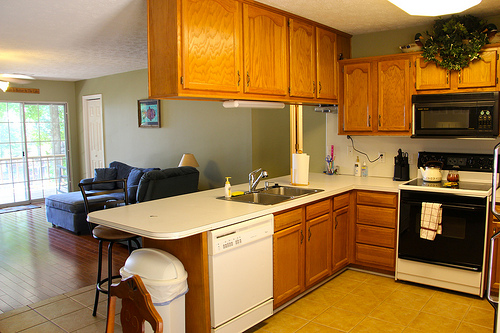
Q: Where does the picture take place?
A: In a house.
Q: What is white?
A: Dishwasher.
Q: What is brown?
A: Cabinets.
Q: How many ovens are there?
A: One.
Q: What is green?
A: Plants.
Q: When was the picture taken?
A: Daytime.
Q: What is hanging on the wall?
A: Painting.